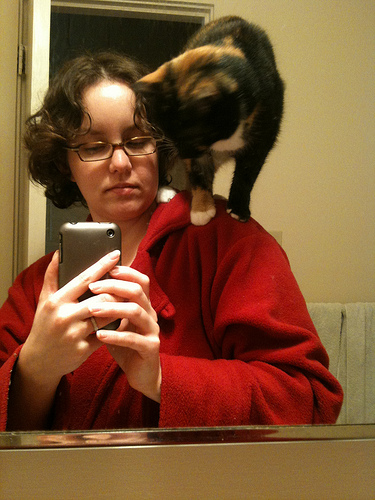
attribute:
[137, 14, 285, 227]
cat — black, brown, orange, calico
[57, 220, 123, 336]
smartphone — modern, gray, grey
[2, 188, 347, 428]
robe — red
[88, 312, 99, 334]
ring — silver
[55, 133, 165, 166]
glasses — brown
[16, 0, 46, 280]
door — open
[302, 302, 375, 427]
towel — white, hanging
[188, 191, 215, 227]
paw — white, brown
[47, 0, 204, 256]
doorway — open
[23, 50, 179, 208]
hair — brown, long